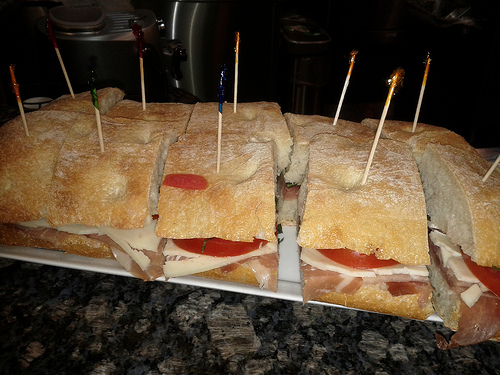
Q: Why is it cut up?
A: Portions.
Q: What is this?
A: A sub.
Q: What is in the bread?
A: Toothpicks.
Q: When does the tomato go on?
A: Last.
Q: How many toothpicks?
A: 10.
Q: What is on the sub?
A: Meat and cheese.